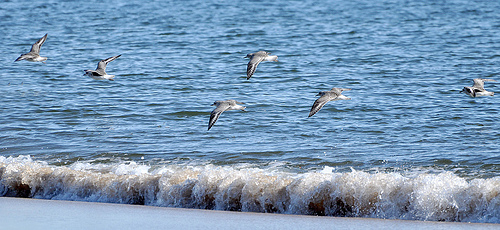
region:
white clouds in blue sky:
[22, 8, 56, 35]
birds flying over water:
[10, 27, 493, 145]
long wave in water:
[0, 149, 498, 229]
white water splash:
[372, 155, 419, 173]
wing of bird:
[205, 103, 234, 133]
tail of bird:
[30, 53, 49, 67]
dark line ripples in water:
[312, 24, 391, 64]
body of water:
[2, 3, 499, 221]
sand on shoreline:
[10, 191, 497, 228]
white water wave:
[1, 150, 498, 226]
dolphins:
[190, 16, 284, 131]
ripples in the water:
[136, 3, 221, 88]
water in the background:
[140, 0, 225, 55]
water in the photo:
[310, 5, 431, 80]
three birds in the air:
[178, 27, 363, 137]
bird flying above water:
[291, 69, 367, 134]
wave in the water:
[134, 127, 321, 227]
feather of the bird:
[233, 52, 274, 85]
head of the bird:
[231, 43, 256, 70]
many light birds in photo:
[0, 3, 492, 161]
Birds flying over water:
[15, 30, 496, 131]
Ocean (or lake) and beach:
[0, 0, 496, 225]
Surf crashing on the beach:
[0, 152, 499, 222]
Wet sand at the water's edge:
[0, 195, 496, 226]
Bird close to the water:
[456, 75, 496, 105]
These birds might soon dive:
[15, 32, 121, 82]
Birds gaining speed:
[207, 49, 351, 130]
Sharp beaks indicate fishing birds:
[206, 48, 493, 128]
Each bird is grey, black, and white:
[16, 33, 494, 133]